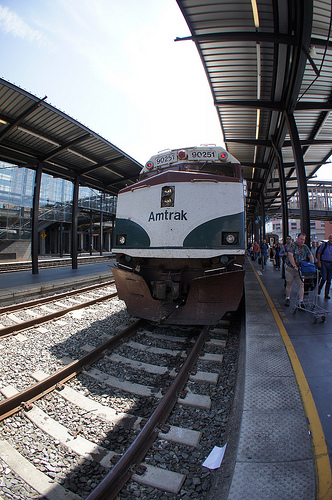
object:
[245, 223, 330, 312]
people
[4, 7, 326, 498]
train station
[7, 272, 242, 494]
tracks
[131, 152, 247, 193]
engine windows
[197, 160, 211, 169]
windshield wpiers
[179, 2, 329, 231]
overhang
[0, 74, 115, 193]
shelter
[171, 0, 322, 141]
shelter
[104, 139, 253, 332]
train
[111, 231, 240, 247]
headlights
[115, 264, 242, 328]
pusher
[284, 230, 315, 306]
man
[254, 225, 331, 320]
passangers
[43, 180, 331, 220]
overpass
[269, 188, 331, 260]
buildings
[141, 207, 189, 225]
word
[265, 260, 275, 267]
paper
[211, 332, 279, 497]
platform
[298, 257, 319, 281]
bag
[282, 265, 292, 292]
pants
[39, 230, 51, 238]
sign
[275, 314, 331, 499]
line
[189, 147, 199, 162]
number